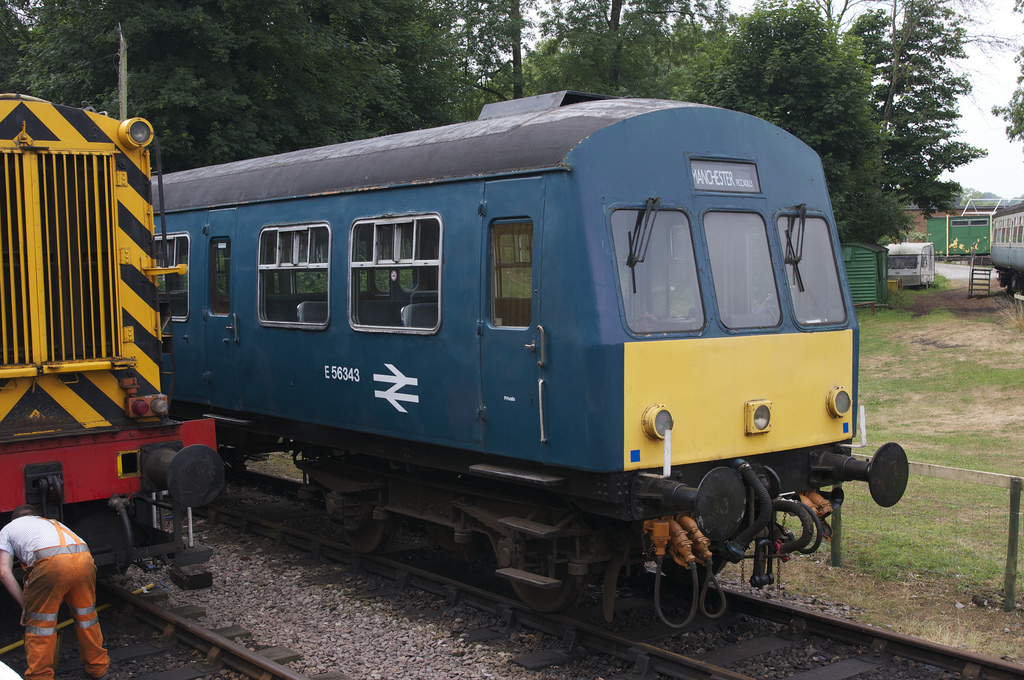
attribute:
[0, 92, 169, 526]
train — black, yellow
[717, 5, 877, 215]
leaves — green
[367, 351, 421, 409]
emblem — white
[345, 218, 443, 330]
window — white, trimmed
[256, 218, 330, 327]
window — white, trimmed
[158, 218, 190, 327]
window — white, trimmed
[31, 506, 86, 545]
suspenders — orange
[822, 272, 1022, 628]
grass — patchy, unhealthy